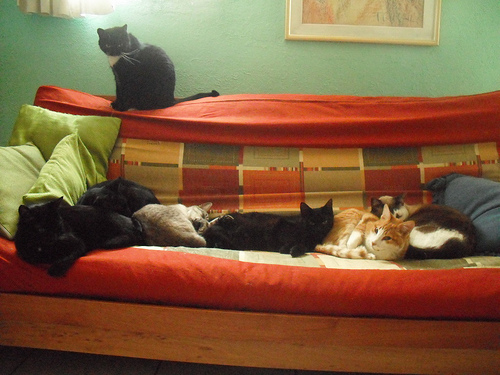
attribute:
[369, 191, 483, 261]
cat — black, white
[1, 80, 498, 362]
futon — taupe, orange, brown, tan, yellow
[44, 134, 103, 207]
pillow — green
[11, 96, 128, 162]
pillow — green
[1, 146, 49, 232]
pillow — green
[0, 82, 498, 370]
sofa — multi-colored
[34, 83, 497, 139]
cover — orange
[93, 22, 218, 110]
cat — black, white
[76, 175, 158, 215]
cat — black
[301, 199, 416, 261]
cat — orange, white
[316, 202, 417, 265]
cat — orange and white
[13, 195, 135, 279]
cat — black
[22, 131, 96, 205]
pillow — green 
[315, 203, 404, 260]
cat — orange, white, short haired, tabby cat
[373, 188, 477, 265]
cat — brown and white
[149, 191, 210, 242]
cat — gray , three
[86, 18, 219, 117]
cat — black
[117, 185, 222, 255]
cat — gray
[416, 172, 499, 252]
pillow — gray, throw pillow, blue